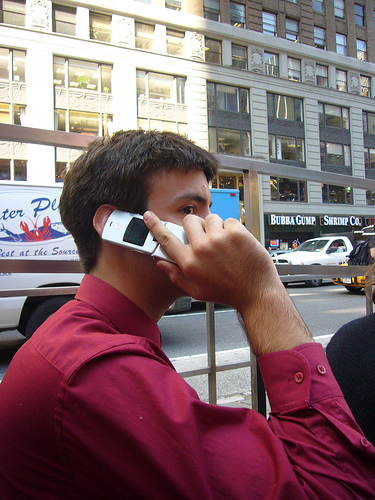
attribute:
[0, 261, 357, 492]
shirt — long, red, sleeve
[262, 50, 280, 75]
window — glass, rectangular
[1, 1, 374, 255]
building — tall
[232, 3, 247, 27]
window — glass, rectangular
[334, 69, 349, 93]
window — glass, rectangular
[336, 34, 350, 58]
window — glass, rectangular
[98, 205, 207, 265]
phone — silver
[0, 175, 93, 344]
truck — white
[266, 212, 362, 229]
lettering — white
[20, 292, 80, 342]
tire — black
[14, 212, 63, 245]
lobster — red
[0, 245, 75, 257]
lettering — blue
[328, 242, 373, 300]
car — yellow